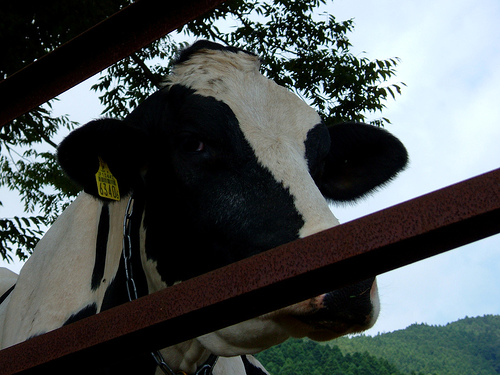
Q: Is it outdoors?
A: Yes, it is outdoors.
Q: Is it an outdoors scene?
A: Yes, it is outdoors.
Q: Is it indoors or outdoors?
A: It is outdoors.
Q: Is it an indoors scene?
A: No, it is outdoors.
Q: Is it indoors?
A: No, it is outdoors.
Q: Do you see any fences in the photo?
A: Yes, there is a fence.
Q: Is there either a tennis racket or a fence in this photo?
A: Yes, there is a fence.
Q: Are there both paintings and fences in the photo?
A: No, there is a fence but no paintings.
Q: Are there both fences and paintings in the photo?
A: No, there is a fence but no paintings.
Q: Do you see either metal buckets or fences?
A: Yes, there is a metal fence.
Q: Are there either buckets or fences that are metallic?
A: Yes, the fence is metallic.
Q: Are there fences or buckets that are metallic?
A: Yes, the fence is metallic.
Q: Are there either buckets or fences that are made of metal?
A: Yes, the fence is made of metal.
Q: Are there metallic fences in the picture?
A: Yes, there is a metal fence.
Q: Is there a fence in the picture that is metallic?
A: Yes, there is a fence that is metallic.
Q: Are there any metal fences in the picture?
A: Yes, there is a fence that is made of metal.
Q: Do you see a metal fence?
A: Yes, there is a fence that is made of metal.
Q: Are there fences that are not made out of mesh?
A: Yes, there is a fence that is made of metal.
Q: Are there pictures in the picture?
A: No, there are no pictures.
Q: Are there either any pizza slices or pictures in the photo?
A: No, there are no pictures or pizza slices.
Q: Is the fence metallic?
A: Yes, the fence is metallic.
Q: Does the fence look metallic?
A: Yes, the fence is metallic.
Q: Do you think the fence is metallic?
A: Yes, the fence is metallic.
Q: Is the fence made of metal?
A: Yes, the fence is made of metal.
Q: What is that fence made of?
A: The fence is made of metal.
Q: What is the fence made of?
A: The fence is made of metal.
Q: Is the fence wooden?
A: No, the fence is metallic.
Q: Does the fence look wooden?
A: No, the fence is metallic.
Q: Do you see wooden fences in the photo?
A: No, there is a fence but it is metallic.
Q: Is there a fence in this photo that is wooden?
A: No, there is a fence but it is metallic.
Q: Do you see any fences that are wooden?
A: No, there is a fence but it is metallic.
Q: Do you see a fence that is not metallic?
A: No, there is a fence but it is metallic.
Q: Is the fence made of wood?
A: No, the fence is made of metal.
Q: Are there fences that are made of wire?
A: No, there is a fence but it is made of metal.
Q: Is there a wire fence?
A: No, there is a fence but it is made of metal.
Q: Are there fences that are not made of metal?
A: No, there is a fence but it is made of metal.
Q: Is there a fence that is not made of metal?
A: No, there is a fence but it is made of metal.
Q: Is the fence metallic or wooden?
A: The fence is metallic.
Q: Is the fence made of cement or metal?
A: The fence is made of metal.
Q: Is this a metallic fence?
A: Yes, this is a metallic fence.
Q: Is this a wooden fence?
A: No, this is a metallic fence.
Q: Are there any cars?
A: No, there are no cars.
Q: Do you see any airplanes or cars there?
A: No, there are no cars or airplanes.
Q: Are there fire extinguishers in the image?
A: No, there are no fire extinguishers.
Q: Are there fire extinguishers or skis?
A: No, there are no fire extinguishers or skis.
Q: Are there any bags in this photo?
A: No, there are no bags.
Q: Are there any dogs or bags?
A: No, there are no bags or dogs.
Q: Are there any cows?
A: Yes, there is a cow.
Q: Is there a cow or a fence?
A: Yes, there is a cow.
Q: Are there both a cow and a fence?
A: Yes, there are both a cow and a fence.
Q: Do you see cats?
A: No, there are no cats.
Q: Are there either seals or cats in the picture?
A: No, there are no cats or seals.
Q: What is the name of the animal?
A: The animal is a cow.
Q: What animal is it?
A: The animal is a cow.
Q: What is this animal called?
A: This is a cow.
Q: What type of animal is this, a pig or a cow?
A: This is a cow.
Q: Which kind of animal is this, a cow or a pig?
A: This is a cow.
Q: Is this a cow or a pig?
A: This is a cow.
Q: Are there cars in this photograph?
A: No, there are no cars.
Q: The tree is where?
A: The tree is on the mountain.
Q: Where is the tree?
A: The tree is on the mountain.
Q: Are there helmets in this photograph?
A: No, there are no helmets.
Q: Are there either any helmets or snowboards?
A: No, there are no helmets or snowboards.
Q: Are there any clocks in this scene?
A: No, there are no clocks.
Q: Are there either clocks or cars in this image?
A: No, there are no clocks or cars.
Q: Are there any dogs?
A: No, there are no dogs.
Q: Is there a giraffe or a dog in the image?
A: No, there are no dogs or giraffes.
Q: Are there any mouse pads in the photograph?
A: No, there are no mouse pads.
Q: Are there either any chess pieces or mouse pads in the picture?
A: No, there are no mouse pads or chess pieces.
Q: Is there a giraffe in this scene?
A: No, there are no giraffes.